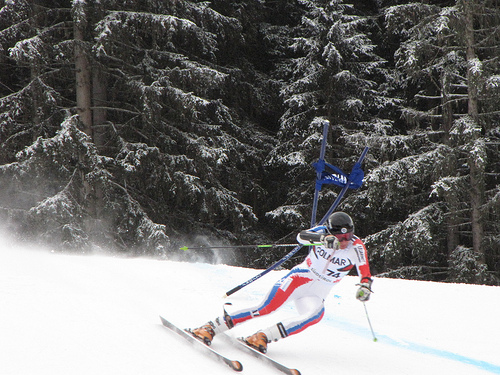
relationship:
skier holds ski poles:
[186, 209, 371, 354] [357, 288, 377, 342]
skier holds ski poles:
[186, 209, 371, 354] [180, 242, 331, 249]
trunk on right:
[428, 32, 497, 292] [429, 15, 496, 265]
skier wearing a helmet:
[186, 209, 371, 354] [323, 212, 353, 250]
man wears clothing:
[193, 212, 370, 362] [215, 226, 371, 347]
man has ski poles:
[179, 208, 376, 355] [176, 239, 330, 252]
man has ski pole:
[179, 208, 376, 355] [356, 300, 381, 344]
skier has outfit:
[186, 209, 371, 354] [209, 227, 371, 341]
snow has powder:
[13, 260, 145, 373] [3, 175, 227, 271]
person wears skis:
[191, 213, 373, 352] [160, 312, 299, 374]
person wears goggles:
[180, 210, 377, 356] [326, 227, 354, 242]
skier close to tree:
[186, 209, 371, 354] [336, 0, 498, 272]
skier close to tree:
[186, 209, 371, 354] [252, 0, 396, 272]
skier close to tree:
[186, 209, 371, 354] [5, 0, 279, 250]